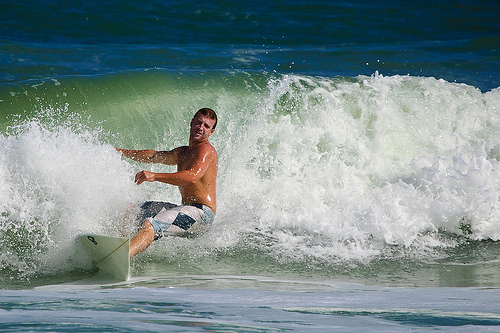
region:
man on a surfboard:
[62, 98, 253, 295]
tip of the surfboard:
[114, 230, 139, 255]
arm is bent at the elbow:
[127, 158, 213, 193]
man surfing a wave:
[4, 56, 493, 298]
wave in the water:
[5, 71, 495, 281]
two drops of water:
[360, 53, 385, 70]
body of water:
[2, 0, 499, 330]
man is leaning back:
[91, 88, 254, 278]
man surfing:
[73, 91, 225, 286]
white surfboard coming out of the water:
[79, 224, 137, 284]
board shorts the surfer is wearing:
[134, 194, 214, 246]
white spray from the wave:
[2, 96, 485, 268]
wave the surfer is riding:
[8, 82, 498, 256]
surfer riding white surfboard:
[52, 110, 248, 271]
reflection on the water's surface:
[425, 251, 499, 298]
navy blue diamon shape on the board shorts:
[170, 208, 199, 234]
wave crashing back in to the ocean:
[13, 82, 498, 251]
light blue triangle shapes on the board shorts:
[151, 206, 214, 240]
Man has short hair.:
[193, 93, 230, 140]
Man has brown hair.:
[191, 105, 231, 125]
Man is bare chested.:
[173, 149, 222, 184]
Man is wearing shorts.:
[153, 189, 221, 271]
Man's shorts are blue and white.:
[125, 203, 231, 250]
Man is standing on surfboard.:
[74, 199, 156, 292]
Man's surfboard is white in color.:
[65, 164, 155, 292]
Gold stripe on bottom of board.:
[97, 244, 134, 261]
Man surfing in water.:
[46, 108, 229, 258]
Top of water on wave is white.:
[125, 129, 375, 198]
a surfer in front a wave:
[52, 80, 243, 298]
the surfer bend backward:
[110, 90, 235, 275]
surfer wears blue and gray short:
[108, 94, 229, 271]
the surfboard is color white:
[66, 219, 141, 293]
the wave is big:
[0, 53, 499, 284]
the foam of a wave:
[230, 70, 495, 251]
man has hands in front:
[95, 90, 231, 266]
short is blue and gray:
[130, 198, 222, 244]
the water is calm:
[0, 280, 495, 326]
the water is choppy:
[0, 65, 499, 262]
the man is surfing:
[50, 88, 250, 315]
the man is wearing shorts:
[103, 178, 220, 257]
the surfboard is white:
[38, 215, 153, 299]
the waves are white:
[217, 30, 470, 267]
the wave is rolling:
[112, 42, 472, 269]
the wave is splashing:
[35, 80, 417, 303]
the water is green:
[37, 48, 279, 180]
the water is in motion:
[136, 45, 471, 270]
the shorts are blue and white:
[117, 180, 226, 254]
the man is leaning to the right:
[71, 80, 256, 317]